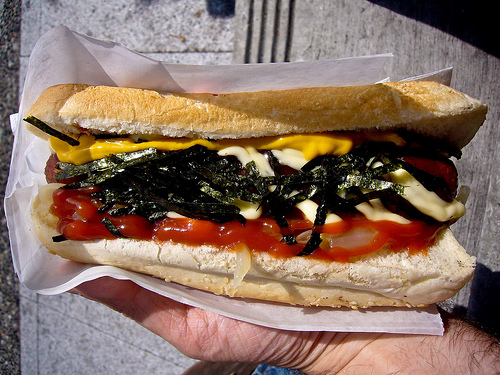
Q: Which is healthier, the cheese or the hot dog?
A: The cheese is healthier than the hot dog.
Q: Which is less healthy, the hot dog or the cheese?
A: The hot dog is less healthy than the cheese.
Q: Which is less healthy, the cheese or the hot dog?
A: The hot dog is less healthy than the cheese.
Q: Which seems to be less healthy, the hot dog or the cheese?
A: The hot dog is less healthy than the cheese.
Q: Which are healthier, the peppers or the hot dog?
A: The peppers are healthier than the hot dog.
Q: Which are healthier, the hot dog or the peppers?
A: The peppers are healthier than the hot dog.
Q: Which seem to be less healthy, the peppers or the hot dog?
A: The hot dog are less healthy than the peppers.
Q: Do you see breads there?
A: Yes, there is a bread.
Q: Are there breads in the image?
A: Yes, there is a bread.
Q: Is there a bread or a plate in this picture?
A: Yes, there is a bread.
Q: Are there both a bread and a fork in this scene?
A: No, there is a bread but no forks.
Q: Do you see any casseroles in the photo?
A: No, there are no casseroles.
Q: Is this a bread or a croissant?
A: This is a bread.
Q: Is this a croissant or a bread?
A: This is a bread.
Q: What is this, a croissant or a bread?
A: This is a bread.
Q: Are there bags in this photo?
A: No, there are no bags.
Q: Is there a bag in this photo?
A: No, there are no bags.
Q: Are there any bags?
A: No, there are no bags.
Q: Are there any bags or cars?
A: No, there are no bags or cars.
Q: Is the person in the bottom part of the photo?
A: Yes, the person is in the bottom of the image.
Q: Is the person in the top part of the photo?
A: No, the person is in the bottom of the image.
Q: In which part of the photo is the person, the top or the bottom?
A: The person is in the bottom of the image.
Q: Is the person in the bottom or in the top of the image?
A: The person is in the bottom of the image.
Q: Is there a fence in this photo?
A: No, there are no fences.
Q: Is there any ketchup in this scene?
A: Yes, there is ketchup.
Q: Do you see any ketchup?
A: Yes, there is ketchup.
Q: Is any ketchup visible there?
A: Yes, there is ketchup.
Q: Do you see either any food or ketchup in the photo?
A: Yes, there is ketchup.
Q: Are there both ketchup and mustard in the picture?
A: Yes, there are both ketchup and mustard.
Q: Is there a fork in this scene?
A: No, there are no forks.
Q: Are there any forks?
A: No, there are no forks.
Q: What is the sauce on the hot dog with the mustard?
A: The sauce is ketchup.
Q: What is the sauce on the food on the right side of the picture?
A: The sauce is ketchup.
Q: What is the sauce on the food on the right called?
A: The sauce is ketchup.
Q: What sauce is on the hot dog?
A: The sauce is ketchup.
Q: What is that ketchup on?
A: The ketchup is on the hot dog.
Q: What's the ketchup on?
A: The ketchup is on the hot dog.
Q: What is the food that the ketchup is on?
A: The food is a hot dog.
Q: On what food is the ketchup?
A: The ketchup is on the hot dog.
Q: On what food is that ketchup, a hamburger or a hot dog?
A: The ketchup is on a hot dog.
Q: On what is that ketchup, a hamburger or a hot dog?
A: The ketchup is on a hot dog.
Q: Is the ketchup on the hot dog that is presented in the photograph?
A: Yes, the ketchup is on the hot dog.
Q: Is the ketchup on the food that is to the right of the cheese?
A: Yes, the ketchup is on the hot dog.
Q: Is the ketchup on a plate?
A: No, the ketchup is on the hot dog.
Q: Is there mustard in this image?
A: Yes, there is mustard.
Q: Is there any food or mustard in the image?
A: Yes, there is mustard.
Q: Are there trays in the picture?
A: No, there are no trays.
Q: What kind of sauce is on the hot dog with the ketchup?
A: The sauce is mustard.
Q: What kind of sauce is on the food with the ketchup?
A: The sauce is mustard.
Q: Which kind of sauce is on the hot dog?
A: The sauce is mustard.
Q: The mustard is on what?
A: The mustard is on the hot dog.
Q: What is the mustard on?
A: The mustard is on the hot dog.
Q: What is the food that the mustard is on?
A: The food is a hot dog.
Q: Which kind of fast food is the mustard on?
A: The mustard is on the hot dog.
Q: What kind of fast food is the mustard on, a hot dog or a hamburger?
A: The mustard is on a hot dog.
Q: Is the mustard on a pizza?
A: No, the mustard is on the hot dog.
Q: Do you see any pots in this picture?
A: No, there are no pots.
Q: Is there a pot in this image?
A: No, there are no pots.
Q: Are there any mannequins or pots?
A: No, there are no pots or mannequins.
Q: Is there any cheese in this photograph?
A: Yes, there is cheese.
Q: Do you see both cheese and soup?
A: No, there is cheese but no soup.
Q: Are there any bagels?
A: No, there are no bagels.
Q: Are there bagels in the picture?
A: No, there are no bagels.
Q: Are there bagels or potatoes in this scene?
A: No, there are no bagels or potatoes.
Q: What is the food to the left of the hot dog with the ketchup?
A: The food is cheese.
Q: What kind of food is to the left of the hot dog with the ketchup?
A: The food is cheese.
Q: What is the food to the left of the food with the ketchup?
A: The food is cheese.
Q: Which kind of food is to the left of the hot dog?
A: The food is cheese.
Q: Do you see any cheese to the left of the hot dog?
A: Yes, there is cheese to the left of the hot dog.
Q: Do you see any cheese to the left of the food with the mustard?
A: Yes, there is cheese to the left of the hot dog.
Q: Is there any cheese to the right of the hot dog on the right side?
A: No, the cheese is to the left of the hot dog.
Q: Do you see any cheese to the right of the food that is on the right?
A: No, the cheese is to the left of the hot dog.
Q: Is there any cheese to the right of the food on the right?
A: No, the cheese is to the left of the hot dog.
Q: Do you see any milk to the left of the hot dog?
A: No, there is cheese to the left of the hot dog.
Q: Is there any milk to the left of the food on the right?
A: No, there is cheese to the left of the hot dog.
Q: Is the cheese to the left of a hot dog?
A: Yes, the cheese is to the left of a hot dog.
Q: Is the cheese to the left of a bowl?
A: No, the cheese is to the left of a hot dog.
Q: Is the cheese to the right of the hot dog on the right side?
A: No, the cheese is to the left of the hot dog.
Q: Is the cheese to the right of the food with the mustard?
A: No, the cheese is to the left of the hot dog.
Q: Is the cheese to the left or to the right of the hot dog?
A: The cheese is to the left of the hot dog.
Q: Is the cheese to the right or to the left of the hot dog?
A: The cheese is to the left of the hot dog.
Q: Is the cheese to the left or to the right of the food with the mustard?
A: The cheese is to the left of the hot dog.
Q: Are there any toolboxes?
A: No, there are no toolboxes.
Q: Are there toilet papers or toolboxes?
A: No, there are no toolboxes or toilet papers.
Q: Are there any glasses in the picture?
A: No, there are no glasses.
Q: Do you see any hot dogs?
A: Yes, there is a hot dog.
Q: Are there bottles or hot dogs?
A: Yes, there is a hot dog.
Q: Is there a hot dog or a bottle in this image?
A: Yes, there is a hot dog.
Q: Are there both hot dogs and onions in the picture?
A: Yes, there are both a hot dog and onions.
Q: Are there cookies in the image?
A: No, there are no cookies.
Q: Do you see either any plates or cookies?
A: No, there are no cookies or plates.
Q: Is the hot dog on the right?
A: Yes, the hot dog is on the right of the image.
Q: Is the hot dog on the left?
A: No, the hot dog is on the right of the image.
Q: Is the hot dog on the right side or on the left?
A: The hot dog is on the right of the image.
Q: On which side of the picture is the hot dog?
A: The hot dog is on the right of the image.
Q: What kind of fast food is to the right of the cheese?
A: The food is a hot dog.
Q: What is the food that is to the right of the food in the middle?
A: The food is a hot dog.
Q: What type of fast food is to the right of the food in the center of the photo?
A: The food is a hot dog.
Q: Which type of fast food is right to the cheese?
A: The food is a hot dog.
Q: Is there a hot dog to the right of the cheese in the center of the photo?
A: Yes, there is a hot dog to the right of the cheese.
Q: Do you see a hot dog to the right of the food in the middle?
A: Yes, there is a hot dog to the right of the cheese.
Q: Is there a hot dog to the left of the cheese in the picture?
A: No, the hot dog is to the right of the cheese.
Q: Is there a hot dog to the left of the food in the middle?
A: No, the hot dog is to the right of the cheese.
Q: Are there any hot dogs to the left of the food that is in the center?
A: No, the hot dog is to the right of the cheese.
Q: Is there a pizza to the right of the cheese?
A: No, there is a hot dog to the right of the cheese.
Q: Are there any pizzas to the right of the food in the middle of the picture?
A: No, there is a hot dog to the right of the cheese.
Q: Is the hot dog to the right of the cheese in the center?
A: Yes, the hot dog is to the right of the cheese.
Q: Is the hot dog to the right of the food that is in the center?
A: Yes, the hot dog is to the right of the cheese.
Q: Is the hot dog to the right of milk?
A: No, the hot dog is to the right of the cheese.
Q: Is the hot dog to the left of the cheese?
A: No, the hot dog is to the right of the cheese.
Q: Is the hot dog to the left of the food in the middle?
A: No, the hot dog is to the right of the cheese.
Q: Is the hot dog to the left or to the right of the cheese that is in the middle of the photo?
A: The hot dog is to the right of the cheese.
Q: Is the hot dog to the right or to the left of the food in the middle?
A: The hot dog is to the right of the cheese.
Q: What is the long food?
A: The food is a bun.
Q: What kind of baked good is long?
A: The baked good is a bun.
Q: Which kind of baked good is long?
A: The baked good is a bun.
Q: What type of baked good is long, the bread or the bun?
A: The bun is long.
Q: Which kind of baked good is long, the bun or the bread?
A: The bun is long.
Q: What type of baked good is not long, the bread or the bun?
A: The bread is not long.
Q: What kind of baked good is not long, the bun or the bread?
A: The bread is not long.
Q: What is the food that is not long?
A: The food is a bread.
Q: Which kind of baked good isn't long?
A: The baked good is a bread.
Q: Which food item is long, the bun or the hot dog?
A: The bun is long.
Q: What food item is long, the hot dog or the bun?
A: The bun is long.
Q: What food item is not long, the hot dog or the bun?
A: The hot dog is not long.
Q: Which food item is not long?
A: The food item is a hot dog.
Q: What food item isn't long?
A: The food item is a hot dog.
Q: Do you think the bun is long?
A: Yes, the bun is long.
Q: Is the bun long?
A: Yes, the bun is long.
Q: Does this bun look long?
A: Yes, the bun is long.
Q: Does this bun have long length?
A: Yes, the bun is long.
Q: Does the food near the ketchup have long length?
A: Yes, the bun is long.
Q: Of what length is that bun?
A: The bun is long.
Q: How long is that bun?
A: The bun is long.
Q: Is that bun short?
A: No, the bun is long.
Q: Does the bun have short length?
A: No, the bun is long.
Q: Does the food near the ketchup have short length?
A: No, the bun is long.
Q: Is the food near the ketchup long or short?
A: The bun is long.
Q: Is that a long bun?
A: Yes, that is a long bun.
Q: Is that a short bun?
A: No, that is a long bun.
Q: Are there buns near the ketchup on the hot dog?
A: Yes, there is a bun near the ketchup.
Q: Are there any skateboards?
A: No, there are no skateboards.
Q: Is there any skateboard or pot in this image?
A: No, there are no skateboards or pots.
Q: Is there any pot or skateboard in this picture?
A: No, there are no skateboards or pots.